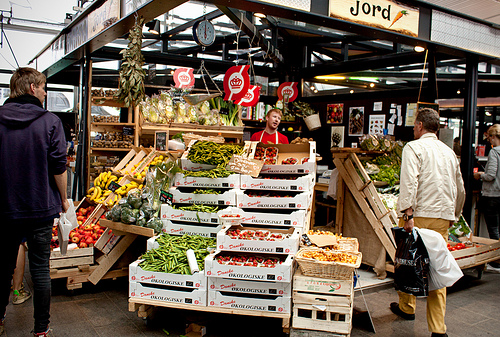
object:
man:
[390, 108, 466, 337]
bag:
[390, 226, 463, 296]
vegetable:
[306, 251, 342, 258]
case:
[217, 225, 301, 255]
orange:
[179, 107, 186, 115]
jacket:
[399, 133, 466, 221]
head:
[413, 108, 440, 139]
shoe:
[390, 302, 415, 320]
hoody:
[0, 103, 48, 122]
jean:
[0, 217, 54, 330]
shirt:
[250, 130, 289, 144]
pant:
[423, 221, 448, 227]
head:
[488, 123, 500, 145]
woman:
[473, 124, 500, 271]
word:
[350, 0, 391, 21]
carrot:
[389, 10, 410, 28]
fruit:
[257, 149, 276, 157]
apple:
[51, 205, 112, 248]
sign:
[223, 65, 260, 107]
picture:
[329, 0, 420, 38]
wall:
[324, 99, 375, 131]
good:
[113, 12, 146, 108]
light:
[145, 19, 160, 35]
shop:
[32, 28, 498, 334]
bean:
[139, 233, 217, 275]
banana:
[86, 155, 163, 206]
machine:
[182, 3, 223, 105]